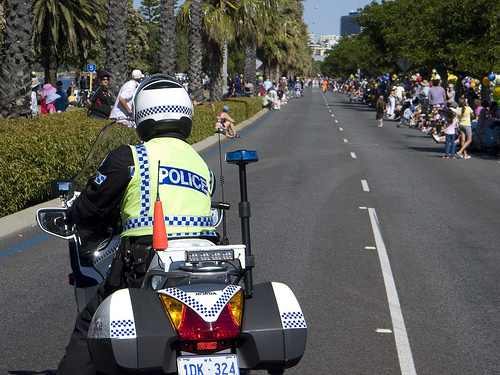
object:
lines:
[367, 206, 419, 374]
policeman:
[67, 72, 220, 374]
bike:
[34, 183, 307, 374]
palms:
[27, 0, 313, 100]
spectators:
[425, 79, 447, 109]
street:
[0, 72, 499, 370]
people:
[211, 105, 243, 141]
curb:
[0, 106, 278, 238]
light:
[222, 150, 268, 168]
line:
[0, 108, 274, 271]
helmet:
[129, 73, 193, 144]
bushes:
[0, 96, 267, 218]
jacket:
[60, 136, 217, 239]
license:
[177, 356, 240, 375]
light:
[179, 298, 238, 342]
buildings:
[317, 34, 342, 47]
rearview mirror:
[35, 207, 73, 239]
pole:
[237, 165, 255, 302]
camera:
[53, 181, 70, 193]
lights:
[160, 295, 183, 331]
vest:
[120, 137, 213, 240]